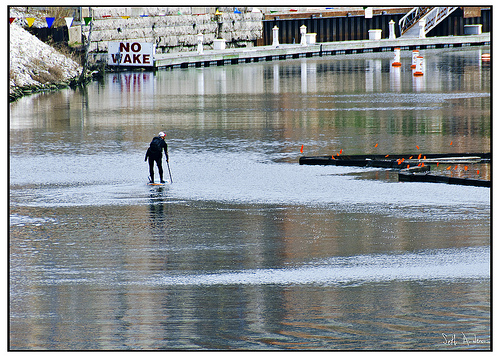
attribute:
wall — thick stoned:
[98, 10, 210, 35]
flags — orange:
[295, 136, 498, 178]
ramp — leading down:
[390, 4, 455, 46]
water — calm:
[1, 43, 496, 351]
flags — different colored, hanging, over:
[14, 7, 261, 30]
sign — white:
[99, 42, 155, 70]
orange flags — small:
[287, 131, 484, 178]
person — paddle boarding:
[138, 123, 175, 190]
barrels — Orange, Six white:
[391, 46, 423, 77]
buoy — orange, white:
[298, 141, 305, 153]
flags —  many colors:
[17, 8, 262, 47]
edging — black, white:
[95, 38, 492, 73]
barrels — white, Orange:
[390, 45, 440, 104]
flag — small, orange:
[298, 144, 307, 157]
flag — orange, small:
[326, 152, 337, 160]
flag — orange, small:
[370, 137, 381, 152]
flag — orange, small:
[444, 139, 454, 149]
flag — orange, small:
[473, 167, 483, 177]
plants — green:
[9, 72, 99, 94]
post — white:
[270, 24, 279, 47]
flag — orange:
[409, 141, 419, 153]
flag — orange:
[286, 135, 316, 159]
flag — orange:
[444, 155, 456, 174]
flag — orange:
[393, 151, 407, 171]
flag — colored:
[38, 14, 58, 33]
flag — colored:
[22, 16, 42, 29]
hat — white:
[155, 132, 166, 141]